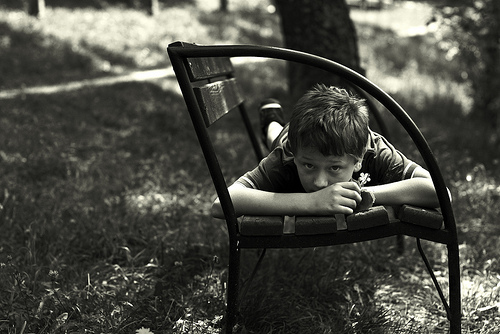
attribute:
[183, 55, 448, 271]
bench — wood , slatted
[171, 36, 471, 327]
bench — one